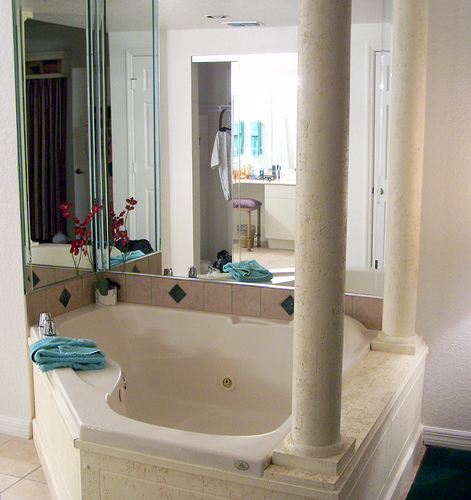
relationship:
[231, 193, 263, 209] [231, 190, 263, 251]
cushion on stool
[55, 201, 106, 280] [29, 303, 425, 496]
plant by tub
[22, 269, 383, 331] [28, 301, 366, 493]
tiling above jicuzzi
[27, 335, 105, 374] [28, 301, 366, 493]
blue towel on jicuzzi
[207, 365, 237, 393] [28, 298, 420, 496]
drain on jicuzzi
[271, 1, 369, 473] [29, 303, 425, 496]
column on tub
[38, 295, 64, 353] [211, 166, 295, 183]
knobs for sink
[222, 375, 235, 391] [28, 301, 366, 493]
drain in jicuzzi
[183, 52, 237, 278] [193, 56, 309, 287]
closet in mirror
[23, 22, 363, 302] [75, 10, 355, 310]
reflection in mirror